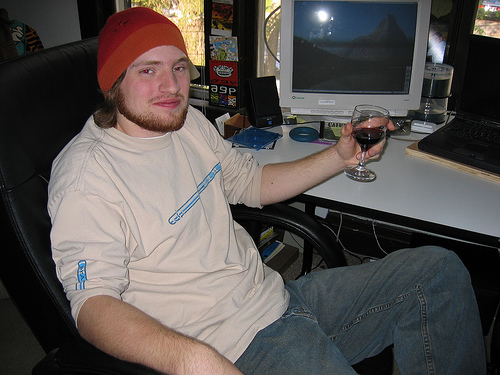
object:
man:
[50, 6, 482, 374]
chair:
[0, 35, 391, 374]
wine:
[360, 133, 374, 142]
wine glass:
[344, 104, 389, 182]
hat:
[99, 6, 188, 91]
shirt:
[46, 111, 292, 363]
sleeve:
[189, 106, 262, 208]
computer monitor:
[279, 0, 430, 116]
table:
[224, 111, 500, 251]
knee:
[404, 245, 476, 298]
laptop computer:
[407, 35, 500, 182]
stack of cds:
[410, 63, 454, 124]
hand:
[336, 117, 395, 165]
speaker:
[244, 76, 282, 128]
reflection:
[319, 12, 328, 22]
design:
[168, 163, 221, 224]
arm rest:
[229, 203, 348, 268]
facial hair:
[116, 90, 189, 131]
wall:
[0, 0, 82, 61]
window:
[114, 0, 212, 100]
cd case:
[227, 125, 283, 149]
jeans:
[232, 246, 488, 375]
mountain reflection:
[338, 16, 413, 59]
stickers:
[209, 36, 238, 61]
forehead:
[133, 46, 186, 62]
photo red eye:
[144, 70, 148, 73]